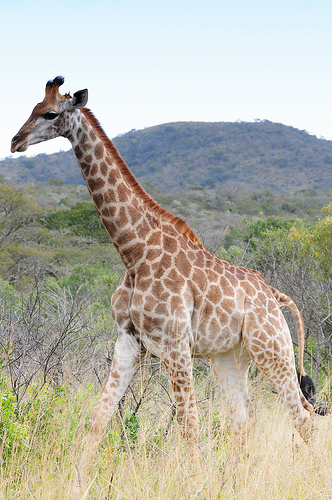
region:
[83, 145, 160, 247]
the long neck of the giraffe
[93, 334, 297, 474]
the four legs of the girraffe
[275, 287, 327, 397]
the giraffes tail with black hair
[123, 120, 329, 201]
hill/ mountain in the backdrop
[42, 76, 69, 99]
the horns of the giraffe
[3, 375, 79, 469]
greenery on the ground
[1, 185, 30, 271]
tree in the background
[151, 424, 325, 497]
long dry grass under the giraffe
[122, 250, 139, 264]
brown spot on the giraffe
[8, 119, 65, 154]
snout of the giraffe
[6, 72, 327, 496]
Giraffe in the meadow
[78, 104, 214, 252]
Brown mane of adult giraffe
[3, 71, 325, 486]
Adult giraffe walking in the meadow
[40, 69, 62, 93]
Two giraffe horns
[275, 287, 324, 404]
Long tail of giraffe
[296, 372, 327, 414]
Tail tuft of giraffe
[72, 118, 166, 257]
Long neck of giraffe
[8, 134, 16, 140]
Giraffe nostril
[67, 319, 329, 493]
Long legs of giraffe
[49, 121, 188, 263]
Brown spotted neck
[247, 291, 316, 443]
hind legs and tale of giraffe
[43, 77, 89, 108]
ears on the giraffe on head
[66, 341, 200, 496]
front legs of giraffe in grass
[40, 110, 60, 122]
one eye of the giraffe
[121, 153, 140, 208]
a hairy section of the giraffe's hair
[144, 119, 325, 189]
a portion of the mountain range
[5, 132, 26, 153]
mouth and nose of giraffe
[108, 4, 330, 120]
portion of the blue sky behind giraffe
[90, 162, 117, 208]
some spots on the giraffe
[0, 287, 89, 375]
bare branches in front of the giraffe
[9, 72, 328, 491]
There is a giraffe.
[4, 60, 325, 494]
The giraffe is walking.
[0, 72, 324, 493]
The giraffe faces left.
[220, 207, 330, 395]
Trees are behind the giraffe.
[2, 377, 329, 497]
The giraffe walks through tall grass.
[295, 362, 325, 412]
The tip of the giraffe's tail is black.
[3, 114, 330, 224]
There is a mountain in the back.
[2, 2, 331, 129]
The sky is blue.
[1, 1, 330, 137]
The sky is clear.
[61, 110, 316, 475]
The giraffe is white and brown.